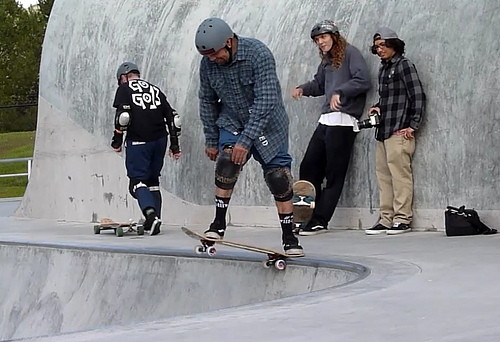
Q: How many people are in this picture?
A: Four.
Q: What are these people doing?
A: Skate Boarding.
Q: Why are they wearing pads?
A: For Protection.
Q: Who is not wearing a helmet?
A: Guy on the right.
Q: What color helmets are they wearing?
A: Gray.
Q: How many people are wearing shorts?
A: One.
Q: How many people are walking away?
A: One.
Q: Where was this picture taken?
A: Skatepark.